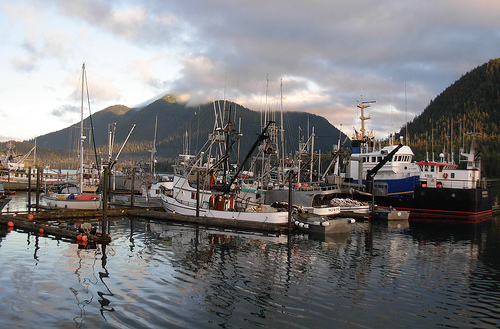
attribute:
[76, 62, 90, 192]
mast — tallest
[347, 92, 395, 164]
mast — yellow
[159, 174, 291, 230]
boat — large, white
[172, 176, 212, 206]
cabin — large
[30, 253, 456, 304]
water — calm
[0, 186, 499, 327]
water — rippling, green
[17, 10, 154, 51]
sky — blue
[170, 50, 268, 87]
cloud — white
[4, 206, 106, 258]
bumper — orange, inflatable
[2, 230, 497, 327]
water — rippling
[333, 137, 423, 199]
boat — large, blue